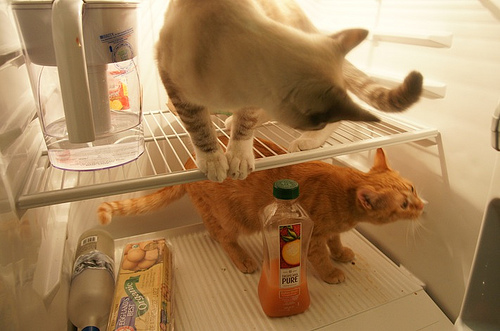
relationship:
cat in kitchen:
[145, 0, 429, 181] [2, 0, 497, 330]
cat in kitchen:
[97, 130, 433, 289] [2, 0, 497, 330]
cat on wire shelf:
[145, 0, 429, 181] [17, 97, 455, 227]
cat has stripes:
[145, 0, 429, 181] [158, 59, 430, 155]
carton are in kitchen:
[107, 237, 172, 331] [2, 0, 497, 330]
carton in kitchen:
[101, 234, 183, 328] [2, 0, 497, 330]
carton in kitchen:
[107, 237, 172, 331] [2, 0, 497, 330]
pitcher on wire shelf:
[6, 1, 161, 178] [17, 97, 455, 227]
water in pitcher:
[28, 107, 151, 174] [6, 1, 161, 178]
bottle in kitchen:
[251, 175, 320, 325] [2, 0, 497, 330]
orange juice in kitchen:
[254, 254, 314, 321] [2, 0, 497, 330]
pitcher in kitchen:
[6, 1, 161, 178] [2, 0, 497, 330]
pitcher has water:
[6, 1, 161, 178] [28, 107, 151, 174]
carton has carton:
[101, 234, 183, 328] [107, 237, 172, 331]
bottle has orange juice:
[251, 175, 320, 325] [254, 254, 314, 321]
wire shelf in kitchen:
[17, 97, 455, 227] [2, 0, 497, 330]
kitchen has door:
[2, 0, 497, 330] [449, 1, 500, 329]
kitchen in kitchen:
[2, 0, 497, 330] [2, 0, 497, 330]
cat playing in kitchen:
[145, 0, 429, 181] [2, 0, 497, 330]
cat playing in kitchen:
[97, 130, 433, 289] [2, 0, 497, 330]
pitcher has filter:
[6, 1, 161, 178] [82, 3, 112, 151]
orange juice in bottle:
[254, 254, 314, 321] [251, 175, 320, 325]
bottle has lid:
[251, 175, 320, 325] [269, 177, 304, 201]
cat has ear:
[97, 130, 433, 289] [351, 178, 380, 217]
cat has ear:
[97, 130, 433, 289] [368, 146, 392, 172]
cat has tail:
[145, 0, 429, 181] [302, 7, 429, 126]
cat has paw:
[97, 130, 433, 289] [312, 261, 352, 289]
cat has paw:
[97, 130, 433, 289] [327, 242, 362, 269]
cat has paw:
[97, 130, 433, 289] [223, 252, 263, 279]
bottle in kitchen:
[68, 228, 114, 330] [2, 0, 497, 330]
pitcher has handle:
[6, 1, 161, 178] [45, 1, 115, 150]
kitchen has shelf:
[2, 0, 497, 330] [114, 222, 452, 330]